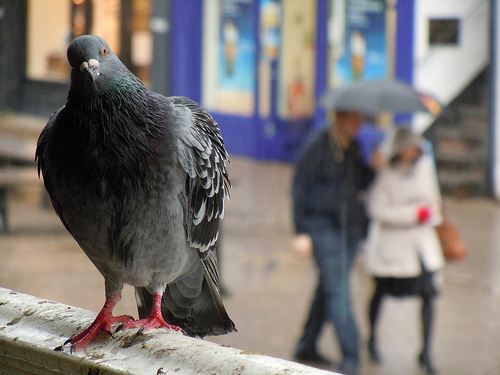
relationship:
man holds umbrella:
[293, 109, 360, 369] [324, 79, 436, 120]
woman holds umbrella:
[366, 127, 444, 371] [324, 79, 436, 120]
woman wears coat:
[366, 127, 444, 371] [363, 158, 449, 274]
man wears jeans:
[293, 109, 360, 369] [295, 232, 366, 359]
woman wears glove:
[366, 127, 444, 371] [417, 206, 427, 221]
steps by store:
[424, 48, 488, 199] [2, 2, 496, 161]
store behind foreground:
[2, 2, 496, 161] [35, 34, 238, 354]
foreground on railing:
[35, 34, 238, 354] [0, 282, 328, 374]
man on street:
[293, 109, 360, 369] [4, 103, 500, 375]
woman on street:
[366, 127, 444, 371] [4, 103, 500, 375]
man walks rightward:
[293, 109, 360, 369] [441, 193, 495, 374]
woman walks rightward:
[366, 127, 444, 371] [441, 193, 495, 374]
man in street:
[293, 109, 360, 369] [4, 103, 500, 375]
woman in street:
[366, 127, 444, 371] [4, 103, 500, 375]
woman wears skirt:
[366, 127, 444, 371] [369, 271, 443, 296]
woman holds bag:
[366, 127, 444, 371] [436, 219, 462, 259]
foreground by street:
[35, 34, 238, 354] [4, 103, 500, 375]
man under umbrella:
[293, 109, 360, 369] [324, 79, 436, 120]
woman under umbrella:
[366, 127, 444, 371] [324, 79, 436, 120]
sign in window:
[219, 1, 258, 90] [206, 2, 318, 113]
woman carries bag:
[366, 127, 444, 371] [436, 219, 462, 259]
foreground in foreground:
[35, 34, 238, 354] [6, 38, 321, 375]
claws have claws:
[64, 292, 135, 354] [65, 322, 183, 344]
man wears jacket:
[293, 109, 360, 369] [290, 126, 372, 240]